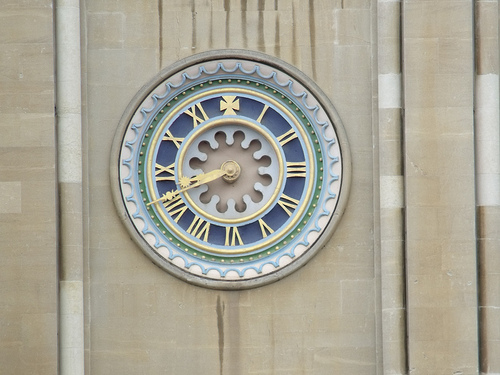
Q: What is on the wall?
A: A clock.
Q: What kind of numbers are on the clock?
A: Roman numerals.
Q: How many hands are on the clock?
A: 2.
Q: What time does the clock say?
A: 8:40.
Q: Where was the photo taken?
A: By a building.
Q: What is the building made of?
A: Stone.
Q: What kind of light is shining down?
A: Sunlight.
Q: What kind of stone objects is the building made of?
A: Blocks.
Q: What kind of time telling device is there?
A: A clock.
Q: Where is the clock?
A: On the building.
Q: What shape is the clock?
A: Round.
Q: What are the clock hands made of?
A: Metal.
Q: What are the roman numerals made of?
A: Metal.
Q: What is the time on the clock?
A: 8:41.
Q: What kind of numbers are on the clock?
A: Roman numerals.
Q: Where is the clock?
A: On a building.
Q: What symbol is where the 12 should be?
A: Cross.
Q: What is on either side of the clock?
A: Pillars.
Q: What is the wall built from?
A: Stone.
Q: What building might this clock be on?
A: Tower.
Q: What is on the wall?
A: A blue and cream clock.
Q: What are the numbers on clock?
A: Roman numerals.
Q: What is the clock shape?
A: Oval.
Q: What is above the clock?
A: A wavy line.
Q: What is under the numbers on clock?
A: Deep blue color.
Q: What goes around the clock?
A: Green dots.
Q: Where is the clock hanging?
A: On side of building.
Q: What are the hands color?
A: Gold.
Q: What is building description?
A: Grey.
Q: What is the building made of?
A: Concrete.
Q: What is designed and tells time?
A: The clock.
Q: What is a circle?
A: The clock.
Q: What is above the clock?
A: Water stains.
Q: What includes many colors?
A: The clock.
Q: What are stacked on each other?
A: Concrete blocks.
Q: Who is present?
A: No one.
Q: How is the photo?
A: Clear.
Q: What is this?
A: Clock.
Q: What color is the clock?
A: Blue.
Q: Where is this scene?
A: Near a clock.